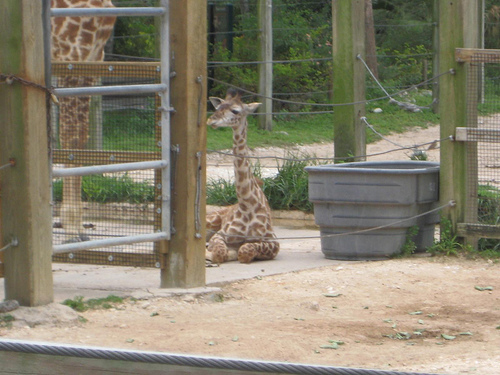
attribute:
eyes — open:
[227, 101, 244, 118]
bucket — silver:
[310, 164, 442, 259]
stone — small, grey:
[321, 289, 344, 303]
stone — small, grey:
[471, 282, 496, 297]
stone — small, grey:
[316, 339, 343, 352]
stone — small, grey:
[148, 308, 163, 322]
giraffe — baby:
[194, 82, 284, 287]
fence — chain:
[2, 3, 489, 305]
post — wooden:
[154, 0, 213, 287]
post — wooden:
[2, 0, 65, 303]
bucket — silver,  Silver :
[305, 158, 441, 261]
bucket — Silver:
[300, 149, 445, 259]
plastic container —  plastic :
[304, 156, 443, 261]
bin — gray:
[289, 151, 442, 251]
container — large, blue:
[305, 159, 439, 260]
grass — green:
[254, 146, 314, 211]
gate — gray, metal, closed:
[43, 5, 173, 255]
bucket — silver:
[311, 133, 418, 246]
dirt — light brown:
[2, 111, 497, 369]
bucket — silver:
[305, 138, 444, 258]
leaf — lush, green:
[279, 61, 283, 65]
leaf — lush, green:
[243, 68, 249, 74]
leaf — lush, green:
[240, 41, 246, 43]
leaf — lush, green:
[244, 20, 247, 22]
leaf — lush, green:
[276, 63, 279, 68]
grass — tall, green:
[49, 147, 485, 248]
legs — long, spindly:
[210, 241, 272, 261]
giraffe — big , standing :
[32, 4, 122, 246]